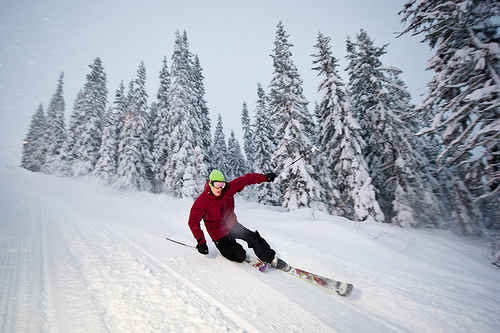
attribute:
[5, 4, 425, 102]
sky — blue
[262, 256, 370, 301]
ski — hard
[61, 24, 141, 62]
clouds — white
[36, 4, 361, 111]
sky — blue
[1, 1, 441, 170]
sky — blue, white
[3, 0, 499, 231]
wooded area — large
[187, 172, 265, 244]
jacket — red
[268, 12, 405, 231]
trees — covered, evergreen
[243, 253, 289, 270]
shoes — black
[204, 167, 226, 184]
hat — green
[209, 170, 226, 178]
hat — green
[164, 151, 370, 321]
man — skier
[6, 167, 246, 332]
tracks — many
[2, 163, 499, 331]
snow — white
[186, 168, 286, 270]
man — tall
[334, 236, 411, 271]
snow — white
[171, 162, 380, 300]
man — wearing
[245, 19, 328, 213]
fir trees — behind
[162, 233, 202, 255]
ski pole — tall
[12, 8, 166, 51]
sky — gray